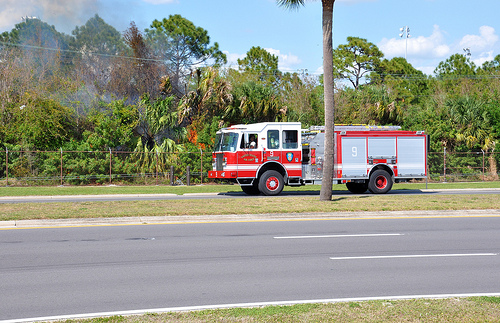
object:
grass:
[0, 194, 500, 220]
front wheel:
[258, 170, 285, 196]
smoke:
[0, 0, 182, 115]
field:
[1, 14, 218, 184]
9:
[269, 151, 273, 157]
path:
[0, 186, 219, 204]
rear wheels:
[368, 169, 393, 194]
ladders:
[310, 126, 402, 131]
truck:
[226, 119, 435, 196]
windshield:
[211, 133, 236, 150]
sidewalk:
[2, 186, 500, 201]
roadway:
[0, 213, 500, 298]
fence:
[0, 144, 500, 188]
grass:
[53, 294, 498, 323]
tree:
[275, 0, 338, 201]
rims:
[258, 170, 285, 196]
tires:
[345, 179, 368, 194]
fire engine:
[207, 122, 429, 197]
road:
[0, 187, 500, 322]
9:
[351, 147, 357, 157]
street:
[1, 189, 499, 321]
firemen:
[246, 134, 257, 150]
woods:
[0, 9, 499, 188]